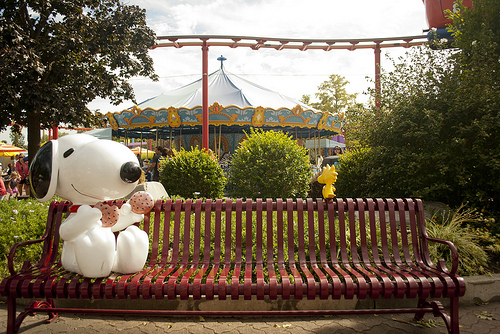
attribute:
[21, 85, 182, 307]
snoopy — white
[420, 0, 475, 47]
coaster car — Roller coaster, red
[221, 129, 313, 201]
bush — green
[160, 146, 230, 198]
bush — green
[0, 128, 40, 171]
tent — red, yellow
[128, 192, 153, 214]
cookie — sprinkled 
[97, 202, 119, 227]
cookie — sprinkled 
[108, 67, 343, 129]
tent — blue, yellow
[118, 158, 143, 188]
nose — black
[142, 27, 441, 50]
track — Roller coaster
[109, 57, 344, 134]
tent — blue, yellow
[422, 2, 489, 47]
rollercoaster car — red, blue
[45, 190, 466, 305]
bench — red, metal